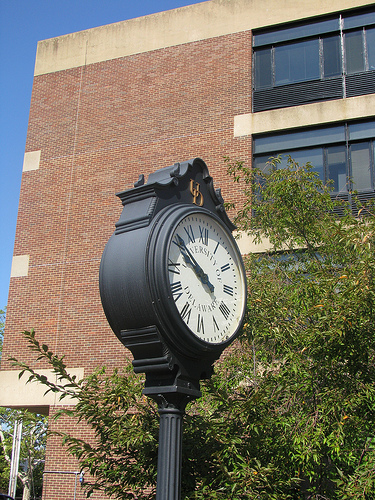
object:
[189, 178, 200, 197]
letters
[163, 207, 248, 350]
clock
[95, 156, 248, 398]
frame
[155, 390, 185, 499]
pole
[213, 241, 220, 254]
numerals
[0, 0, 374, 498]
building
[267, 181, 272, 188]
leaves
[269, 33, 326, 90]
windows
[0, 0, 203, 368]
sky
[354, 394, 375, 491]
trees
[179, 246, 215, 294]
hands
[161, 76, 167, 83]
bricks